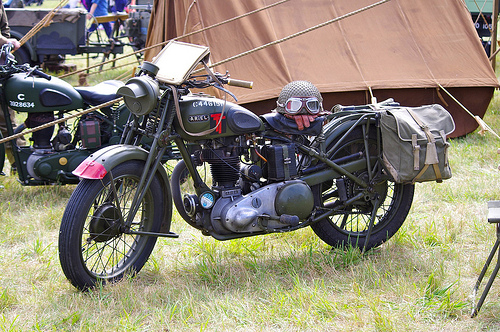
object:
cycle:
[50, 33, 454, 297]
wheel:
[48, 144, 189, 294]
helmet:
[268, 79, 326, 118]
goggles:
[282, 95, 305, 116]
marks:
[210, 112, 231, 135]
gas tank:
[172, 94, 266, 142]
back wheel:
[300, 113, 421, 251]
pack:
[378, 103, 458, 183]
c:
[191, 101, 198, 108]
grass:
[62, 227, 464, 331]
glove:
[284, 114, 321, 131]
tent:
[132, 0, 499, 136]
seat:
[257, 114, 332, 137]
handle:
[226, 76, 258, 90]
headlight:
[110, 77, 162, 118]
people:
[118, 7, 149, 62]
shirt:
[89, 2, 112, 23]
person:
[79, 0, 118, 42]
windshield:
[136, 32, 217, 89]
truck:
[0, 0, 140, 76]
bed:
[0, 0, 89, 33]